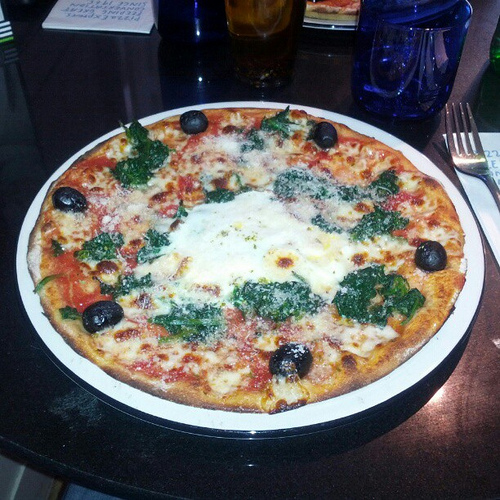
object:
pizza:
[25, 107, 465, 413]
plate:
[14, 100, 489, 440]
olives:
[269, 340, 312, 380]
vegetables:
[338, 263, 423, 328]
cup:
[353, 0, 473, 118]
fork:
[445, 102, 499, 213]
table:
[2, 2, 499, 498]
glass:
[213, 0, 314, 92]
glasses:
[378, 27, 429, 99]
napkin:
[439, 130, 500, 272]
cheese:
[154, 191, 357, 302]